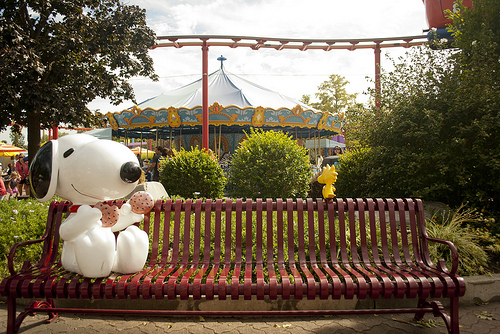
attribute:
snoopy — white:
[21, 85, 182, 307]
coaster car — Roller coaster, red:
[420, 0, 475, 47]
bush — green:
[221, 129, 313, 201]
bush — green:
[160, 146, 230, 198]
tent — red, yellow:
[0, 128, 40, 171]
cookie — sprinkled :
[128, 192, 153, 214]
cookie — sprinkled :
[97, 202, 119, 227]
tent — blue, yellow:
[108, 67, 343, 129]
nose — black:
[118, 158, 143, 188]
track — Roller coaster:
[142, 27, 441, 50]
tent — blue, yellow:
[109, 57, 344, 134]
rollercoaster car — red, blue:
[422, 2, 489, 47]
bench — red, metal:
[45, 190, 466, 305]